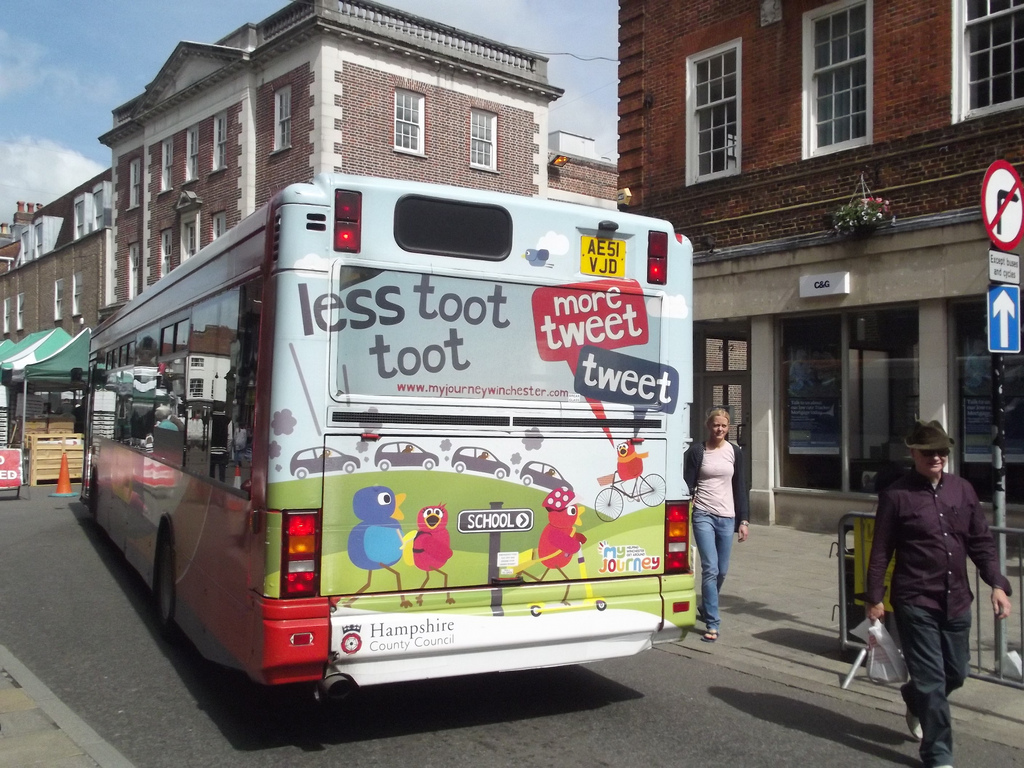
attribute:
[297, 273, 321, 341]
letter — black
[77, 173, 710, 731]
bus — colorful city 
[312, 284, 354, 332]
letter — black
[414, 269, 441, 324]
letter — black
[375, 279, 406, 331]
letter — black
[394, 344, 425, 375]
letter — black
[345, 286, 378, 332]
letter — black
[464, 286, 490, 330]
letter — black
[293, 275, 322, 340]
letter — black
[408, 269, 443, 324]
letter — black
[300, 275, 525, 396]
bus — black letter 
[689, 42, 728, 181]
building — window 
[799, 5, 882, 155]
building — window 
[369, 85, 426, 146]
building — window 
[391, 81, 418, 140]
building — window 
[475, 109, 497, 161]
building — window 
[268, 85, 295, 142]
building — window 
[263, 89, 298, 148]
building — window 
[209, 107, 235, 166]
building — window 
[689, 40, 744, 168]
building — window 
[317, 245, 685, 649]
bus — back , mural 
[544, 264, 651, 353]
sign — white tweet, red 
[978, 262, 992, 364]
sign — white tweet, blue 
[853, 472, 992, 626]
shirt — black 